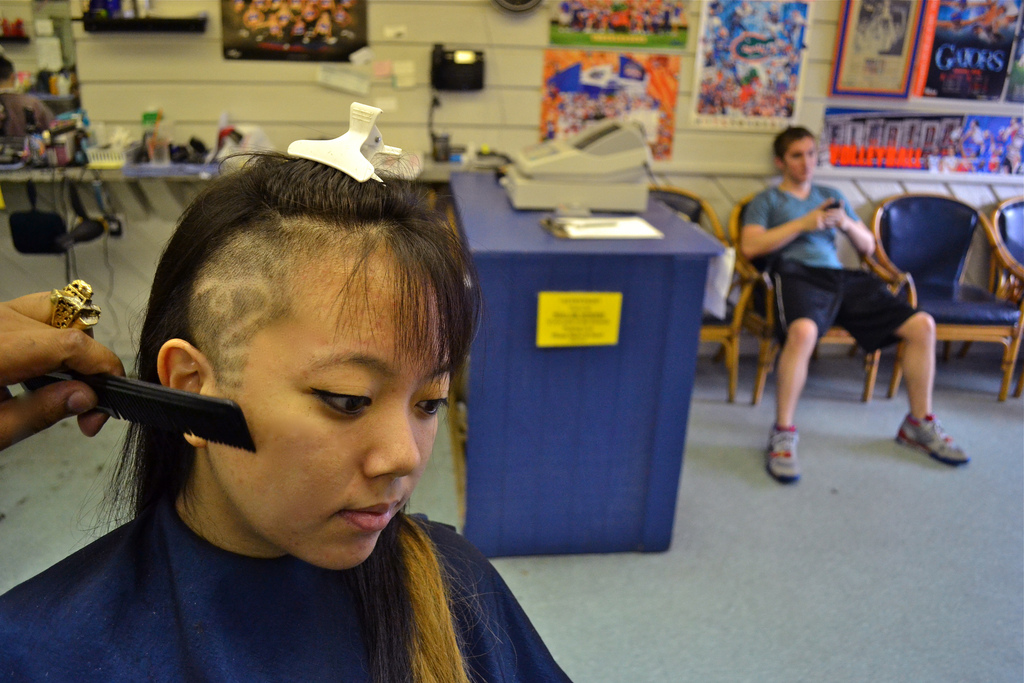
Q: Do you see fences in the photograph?
A: No, there are no fences.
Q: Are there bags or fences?
A: No, there are no fences or bags.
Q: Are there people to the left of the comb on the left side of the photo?
A: Yes, there is a person to the left of the comb.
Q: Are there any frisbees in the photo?
A: No, there are no frisbees.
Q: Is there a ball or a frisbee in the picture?
A: No, there are no frisbees or balls.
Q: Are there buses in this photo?
A: No, there are no buses.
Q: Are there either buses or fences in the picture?
A: No, there are no buses or fences.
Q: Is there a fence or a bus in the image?
A: No, there are no buses or fences.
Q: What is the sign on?
A: The sign is on the counter.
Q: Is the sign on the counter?
A: Yes, the sign is on the counter.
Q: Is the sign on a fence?
A: No, the sign is on the counter.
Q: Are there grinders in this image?
A: No, there are no grinders.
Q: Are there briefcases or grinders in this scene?
A: No, there are no grinders or briefcases.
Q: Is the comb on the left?
A: Yes, the comb is on the left of the image.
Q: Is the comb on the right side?
A: No, the comb is on the left of the image.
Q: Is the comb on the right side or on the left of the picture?
A: The comb is on the left of the image.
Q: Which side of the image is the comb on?
A: The comb is on the left of the image.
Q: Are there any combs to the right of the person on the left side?
A: Yes, there is a comb to the right of the person.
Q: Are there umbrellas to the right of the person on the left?
A: No, there is a comb to the right of the person.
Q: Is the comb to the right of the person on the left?
A: Yes, the comb is to the right of the person.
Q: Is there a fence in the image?
A: No, there are no fences.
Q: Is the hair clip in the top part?
A: Yes, the hair clip is in the top of the image.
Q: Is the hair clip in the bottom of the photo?
A: No, the hair clip is in the top of the image.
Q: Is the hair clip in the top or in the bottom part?
A: The hair clip is in the top of the image.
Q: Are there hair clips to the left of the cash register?
A: Yes, there is a hair clip to the left of the cash register.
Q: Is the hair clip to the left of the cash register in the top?
A: Yes, the hair clip is to the left of the cash register.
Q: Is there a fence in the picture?
A: No, there are no fences.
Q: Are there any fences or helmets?
A: No, there are no fences or helmets.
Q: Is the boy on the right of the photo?
A: Yes, the boy is on the right of the image.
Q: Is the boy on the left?
A: No, the boy is on the right of the image.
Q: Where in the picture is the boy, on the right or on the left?
A: The boy is on the right of the image.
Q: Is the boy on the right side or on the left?
A: The boy is on the right of the image.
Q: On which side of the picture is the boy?
A: The boy is on the right of the image.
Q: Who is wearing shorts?
A: The boy is wearing shorts.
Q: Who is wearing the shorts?
A: The boy is wearing shorts.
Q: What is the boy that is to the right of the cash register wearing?
A: The boy is wearing shorts.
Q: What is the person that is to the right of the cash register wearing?
A: The boy is wearing shorts.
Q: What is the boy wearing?
A: The boy is wearing shorts.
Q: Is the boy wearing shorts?
A: Yes, the boy is wearing shorts.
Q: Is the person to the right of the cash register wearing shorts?
A: Yes, the boy is wearing shorts.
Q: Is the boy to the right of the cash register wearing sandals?
A: No, the boy is wearing shorts.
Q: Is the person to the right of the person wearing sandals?
A: No, the boy is wearing shorts.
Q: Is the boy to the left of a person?
A: No, the boy is to the right of a person.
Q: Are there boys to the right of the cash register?
A: Yes, there is a boy to the right of the cash register.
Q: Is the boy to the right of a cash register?
A: Yes, the boy is to the right of a cash register.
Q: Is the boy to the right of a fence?
A: No, the boy is to the right of a cash register.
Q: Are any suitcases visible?
A: No, there are no suitcases.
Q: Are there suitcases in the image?
A: No, there are no suitcases.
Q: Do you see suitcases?
A: No, there are no suitcases.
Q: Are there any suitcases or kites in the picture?
A: No, there are no suitcases or kites.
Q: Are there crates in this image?
A: No, there are no crates.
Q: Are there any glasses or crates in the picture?
A: No, there are no crates or glasses.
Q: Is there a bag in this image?
A: No, there are no bags.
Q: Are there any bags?
A: No, there are no bags.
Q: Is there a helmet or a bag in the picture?
A: No, there are no bags or helmets.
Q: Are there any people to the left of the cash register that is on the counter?
A: Yes, there is a person to the left of the cash register.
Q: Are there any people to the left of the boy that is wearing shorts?
A: Yes, there is a person to the left of the boy.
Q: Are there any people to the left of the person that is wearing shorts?
A: Yes, there is a person to the left of the boy.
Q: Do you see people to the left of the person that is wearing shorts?
A: Yes, there is a person to the left of the boy.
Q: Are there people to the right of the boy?
A: No, the person is to the left of the boy.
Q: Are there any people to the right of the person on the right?
A: No, the person is to the left of the boy.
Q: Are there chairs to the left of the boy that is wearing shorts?
A: No, there is a person to the left of the boy.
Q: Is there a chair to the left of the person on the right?
A: No, there is a person to the left of the boy.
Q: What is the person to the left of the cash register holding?
A: The person is holding the comb.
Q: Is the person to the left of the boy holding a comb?
A: Yes, the person is holding a comb.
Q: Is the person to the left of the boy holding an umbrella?
A: No, the person is holding a comb.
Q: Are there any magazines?
A: No, there are no magazines.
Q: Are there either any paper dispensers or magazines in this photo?
A: No, there are no magazines or paper dispensers.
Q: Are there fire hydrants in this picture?
A: No, there are no fire hydrants.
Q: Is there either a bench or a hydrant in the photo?
A: No, there are no fire hydrants or benches.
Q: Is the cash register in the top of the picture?
A: Yes, the cash register is in the top of the image.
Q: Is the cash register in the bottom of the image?
A: No, the cash register is in the top of the image.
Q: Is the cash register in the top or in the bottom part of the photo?
A: The cash register is in the top of the image.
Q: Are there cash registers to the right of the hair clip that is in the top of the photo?
A: Yes, there is a cash register to the right of the hair clip.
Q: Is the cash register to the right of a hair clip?
A: Yes, the cash register is to the right of a hair clip.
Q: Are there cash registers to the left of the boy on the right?
A: Yes, there is a cash register to the left of the boy.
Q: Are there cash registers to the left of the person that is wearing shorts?
A: Yes, there is a cash register to the left of the boy.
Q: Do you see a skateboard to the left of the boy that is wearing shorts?
A: No, there is a cash register to the left of the boy.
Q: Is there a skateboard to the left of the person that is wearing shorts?
A: No, there is a cash register to the left of the boy.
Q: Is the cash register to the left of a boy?
A: Yes, the cash register is to the left of a boy.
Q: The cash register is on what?
A: The cash register is on the counter.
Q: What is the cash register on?
A: The cash register is on the counter.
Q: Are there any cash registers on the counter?
A: Yes, there is a cash register on the counter.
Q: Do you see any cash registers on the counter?
A: Yes, there is a cash register on the counter.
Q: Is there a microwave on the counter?
A: No, there is a cash register on the counter.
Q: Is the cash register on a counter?
A: Yes, the cash register is on a counter.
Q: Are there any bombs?
A: No, there are no bombs.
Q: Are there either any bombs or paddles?
A: No, there are no bombs or paddles.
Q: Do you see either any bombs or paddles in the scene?
A: No, there are no bombs or paddles.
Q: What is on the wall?
A: The poster is on the wall.